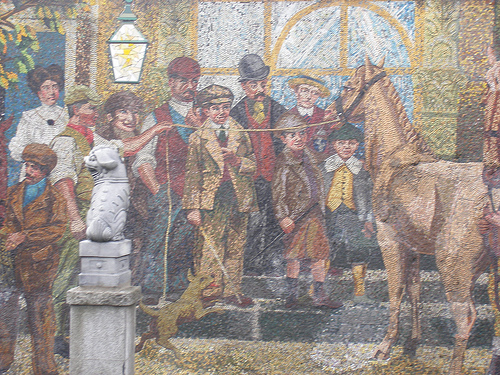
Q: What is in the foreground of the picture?
A: A tall white statue.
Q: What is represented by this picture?
A: A crowd of people meeting outside.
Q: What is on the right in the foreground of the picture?
A: A horse.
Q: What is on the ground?
A: A black line.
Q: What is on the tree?
A: Leaves.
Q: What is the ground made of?
A: Bricks.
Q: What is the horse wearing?
A: Bridle.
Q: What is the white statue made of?
A: Stone.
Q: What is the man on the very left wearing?
A: Brown jacket with blue scarf.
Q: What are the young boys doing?
A: Looking and admiring a horse.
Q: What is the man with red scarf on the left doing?
A: Holding horse's reins.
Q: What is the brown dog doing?
A: Barking at the horse.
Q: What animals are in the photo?
A: Dog and horse.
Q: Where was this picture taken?
A: Art gallery.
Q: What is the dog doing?
A: Barking at horse.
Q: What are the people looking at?
A: The horse.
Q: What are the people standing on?
A: Steps.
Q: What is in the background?
A: Windows.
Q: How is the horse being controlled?
A: Rope.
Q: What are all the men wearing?
A: Hats.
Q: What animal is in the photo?
A: A horse.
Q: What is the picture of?
A: A painting.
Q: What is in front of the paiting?
A: A grey stone statue.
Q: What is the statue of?
A: A dog.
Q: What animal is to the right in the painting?
A: A horse.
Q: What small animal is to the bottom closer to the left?
A: A dog.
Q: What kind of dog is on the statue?
A: A pug.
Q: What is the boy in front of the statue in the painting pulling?
A: The horse.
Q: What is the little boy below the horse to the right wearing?
A: A vest.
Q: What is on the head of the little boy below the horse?
A: A black hat.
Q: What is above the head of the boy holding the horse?
A: A light fixture.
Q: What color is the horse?
A: Brown.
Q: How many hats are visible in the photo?
A: Nine.